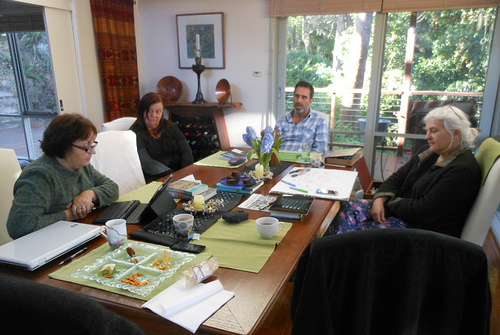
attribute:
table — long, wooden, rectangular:
[8, 144, 345, 334]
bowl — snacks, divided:
[72, 237, 197, 302]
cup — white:
[255, 213, 287, 241]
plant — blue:
[239, 121, 287, 179]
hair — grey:
[425, 100, 477, 152]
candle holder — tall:
[187, 197, 228, 215]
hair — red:
[142, 89, 164, 118]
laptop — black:
[95, 174, 174, 225]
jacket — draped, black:
[297, 227, 494, 332]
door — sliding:
[367, 3, 492, 196]